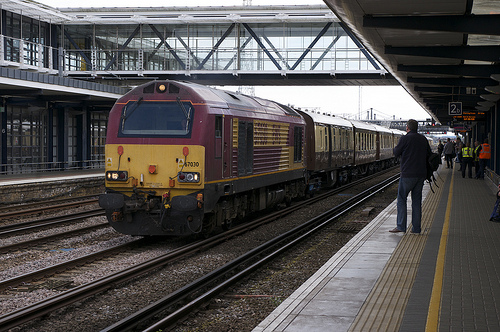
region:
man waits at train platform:
[342, 112, 497, 245]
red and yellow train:
[68, 79, 466, 239]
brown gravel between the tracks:
[1, 106, 458, 329]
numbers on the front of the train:
[93, 72, 222, 202]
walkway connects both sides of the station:
[7, 2, 480, 105]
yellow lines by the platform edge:
[353, 144, 498, 330]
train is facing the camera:
[80, 70, 474, 257]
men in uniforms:
[428, 124, 499, 191]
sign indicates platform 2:
[432, 87, 477, 194]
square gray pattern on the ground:
[411, 149, 495, 324]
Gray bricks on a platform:
[451, 255, 497, 329]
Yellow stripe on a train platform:
[424, 254, 441, 330]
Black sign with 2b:
[447, 100, 462, 116]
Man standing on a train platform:
[391, 116, 428, 234]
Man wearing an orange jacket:
[477, 143, 491, 157]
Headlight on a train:
[153, 83, 170, 91]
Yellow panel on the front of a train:
[107, 144, 203, 188]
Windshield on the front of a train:
[121, 100, 191, 134]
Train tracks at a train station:
[1, 185, 256, 327]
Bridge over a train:
[63, 8, 398, 81]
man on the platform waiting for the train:
[383, 113, 441, 238]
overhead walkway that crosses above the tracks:
[66, 9, 380, 80]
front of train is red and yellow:
[101, 80, 212, 235]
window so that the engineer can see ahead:
[124, 100, 190, 137]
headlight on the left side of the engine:
[105, 169, 129, 181]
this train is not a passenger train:
[121, 80, 408, 204]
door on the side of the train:
[212, 117, 233, 178]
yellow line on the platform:
[430, 195, 458, 330]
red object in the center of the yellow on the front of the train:
[146, 165, 156, 176]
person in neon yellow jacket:
[458, 145, 473, 160]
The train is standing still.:
[93, 83, 385, 198]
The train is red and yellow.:
[100, 78, 382, 192]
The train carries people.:
[84, 76, 421, 206]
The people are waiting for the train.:
[386, 117, 492, 215]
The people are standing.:
[385, 108, 488, 208]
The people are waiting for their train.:
[380, 116, 496, 217]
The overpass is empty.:
[36, 15, 401, 92]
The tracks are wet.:
[13, 212, 266, 315]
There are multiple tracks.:
[13, 212, 268, 324]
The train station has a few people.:
[10, 8, 480, 322]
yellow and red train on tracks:
[90, 70, 392, 241]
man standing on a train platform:
[380, 109, 452, 240]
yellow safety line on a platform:
[429, 176, 454, 330]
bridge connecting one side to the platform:
[63, 13, 392, 86]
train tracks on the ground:
[13, 255, 218, 330]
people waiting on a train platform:
[444, 124, 498, 187]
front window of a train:
[114, 93, 202, 142]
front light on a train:
[147, 79, 177, 102]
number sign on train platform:
[441, 93, 468, 120]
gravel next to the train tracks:
[261, 263, 297, 292]